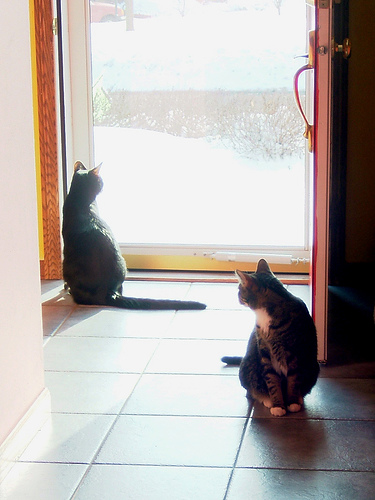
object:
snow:
[94, 125, 304, 246]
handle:
[334, 37, 352, 60]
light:
[49, 430, 147, 490]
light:
[45, 313, 148, 406]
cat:
[220, 257, 321, 417]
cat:
[61, 160, 206, 310]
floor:
[0, 279, 375, 500]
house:
[0, 0, 375, 499]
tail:
[107, 290, 208, 310]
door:
[292, 1, 352, 364]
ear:
[235, 268, 249, 286]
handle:
[292, 30, 315, 153]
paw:
[269, 404, 287, 417]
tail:
[221, 355, 244, 365]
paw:
[287, 400, 303, 412]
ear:
[88, 160, 105, 176]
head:
[235, 258, 280, 311]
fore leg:
[256, 327, 285, 406]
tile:
[93, 413, 247, 468]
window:
[55, 0, 313, 262]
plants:
[91, 74, 306, 162]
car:
[90, 0, 125, 25]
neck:
[249, 277, 293, 324]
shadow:
[250, 401, 329, 492]